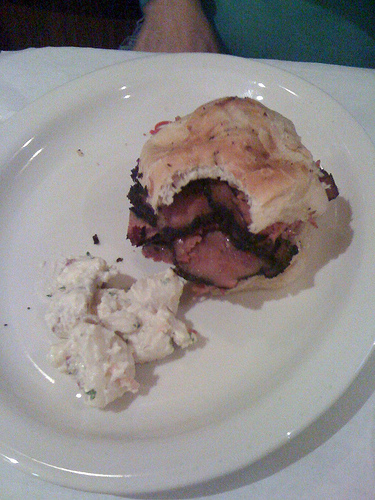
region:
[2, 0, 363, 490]
the plate is on the table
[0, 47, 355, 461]
the plate is round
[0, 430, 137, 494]
the light is reflecting on the plate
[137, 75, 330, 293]
the sandwich has a bite in it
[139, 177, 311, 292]
the meat is pink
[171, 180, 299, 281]
the edges of the meat is black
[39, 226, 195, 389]
potato salad on the plate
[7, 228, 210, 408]
the potato salad is white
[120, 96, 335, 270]
the bread is white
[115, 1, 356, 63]
a persons hand is on the table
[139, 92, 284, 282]
a half eaten sandwich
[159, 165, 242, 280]
meat inside the sandwich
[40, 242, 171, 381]
some kind of food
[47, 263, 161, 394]
food with green in it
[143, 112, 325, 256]
bread has bite taken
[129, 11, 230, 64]
can see hand of person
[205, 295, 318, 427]
a large white plate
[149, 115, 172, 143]
small red round object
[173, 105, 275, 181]
black dots on bread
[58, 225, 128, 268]
black crumbs on plate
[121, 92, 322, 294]
a beef sandwich on a plate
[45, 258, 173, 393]
small portion of potato salad on a plate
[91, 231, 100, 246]
small crumb of beef on plate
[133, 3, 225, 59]
someone's hand just off the table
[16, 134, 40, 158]
light reflecting off the white ceramic plate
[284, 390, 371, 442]
shadow of white plate on table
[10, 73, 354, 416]
sandwich and salad on a plate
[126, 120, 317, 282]
someone has taken a bite out of this sandwich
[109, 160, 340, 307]
pink roast beef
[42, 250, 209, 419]
small dollop of potato salad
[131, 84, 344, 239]
light brown butter milk biscuit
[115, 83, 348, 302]
small sandwich with a bite taken out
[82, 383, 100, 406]
small green fleck of seasoning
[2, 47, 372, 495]
shiny white porcelain plate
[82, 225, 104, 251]
small black crumb on the plate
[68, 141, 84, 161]
small white crumb on the plate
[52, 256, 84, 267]
small pink fleck of potato skin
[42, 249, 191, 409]
Potatoes on a plate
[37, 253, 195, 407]
Potatoes are on a plate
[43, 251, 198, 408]
Potatoes on a white plate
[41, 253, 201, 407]
Potatoes are on a white plate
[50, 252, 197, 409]
Potatoes on a round plate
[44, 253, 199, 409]
Potatoes are on a round plate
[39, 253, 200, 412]
Potatoes are on a round white plate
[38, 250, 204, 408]
Potatoes on a round white plate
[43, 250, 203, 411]
Potato salad on a white plate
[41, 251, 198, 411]
Potato salad are on a white plate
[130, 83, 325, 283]
meat sandwich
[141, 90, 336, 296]
sandwich on white plate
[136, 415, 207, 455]
shiny white plate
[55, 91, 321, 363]
shiny white plate with food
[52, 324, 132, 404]
white potato salad on white plate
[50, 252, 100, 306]
white potato salad on white plate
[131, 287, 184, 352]
white potato salad on white plate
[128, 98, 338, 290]
a biscuit and meat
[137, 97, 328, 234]
the biscuit is brown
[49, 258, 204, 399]
the food is white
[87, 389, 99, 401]
green part of food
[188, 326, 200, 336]
orange part of food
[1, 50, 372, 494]
the plate is white